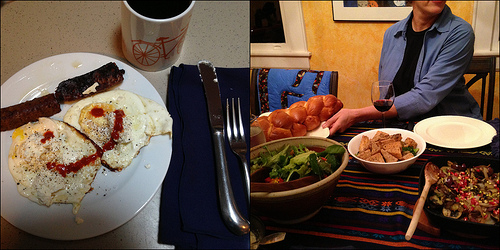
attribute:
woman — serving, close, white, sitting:
[342, 0, 490, 128]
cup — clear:
[363, 75, 399, 122]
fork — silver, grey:
[218, 96, 258, 211]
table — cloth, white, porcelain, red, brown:
[255, 101, 499, 249]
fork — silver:
[224, 95, 250, 207]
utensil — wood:
[400, 160, 441, 240]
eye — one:
[34, 124, 60, 150]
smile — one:
[45, 109, 125, 177]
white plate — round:
[0, 51, 172, 240]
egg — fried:
[60, 87, 163, 172]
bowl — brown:
[249, 134, 350, 223]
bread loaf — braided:
[250, 92, 344, 146]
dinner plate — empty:
[410, 111, 484, 156]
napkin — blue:
[157, 60, 246, 248]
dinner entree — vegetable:
[428, 161, 484, 235]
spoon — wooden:
[403, 159, 438, 241]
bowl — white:
[346, 124, 427, 175]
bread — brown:
[355, 129, 417, 164]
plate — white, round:
[2, 48, 174, 244]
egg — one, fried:
[8, 115, 102, 206]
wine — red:
[372, 97, 396, 114]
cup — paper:
[116, 0, 195, 71]